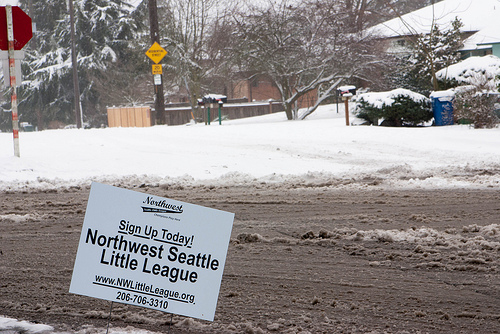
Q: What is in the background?
A: Snow.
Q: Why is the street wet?
A: Slushy snow.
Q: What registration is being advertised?
A: Northwest Seattle Little League.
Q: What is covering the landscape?
A: Snow.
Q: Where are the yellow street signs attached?
A: Telephone pole.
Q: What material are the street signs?
A: Metal.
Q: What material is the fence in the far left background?
A: Wood.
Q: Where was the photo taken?
A: Seattle.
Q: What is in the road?
A: Slush.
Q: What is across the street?
A: Houses.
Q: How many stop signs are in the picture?
A: One.